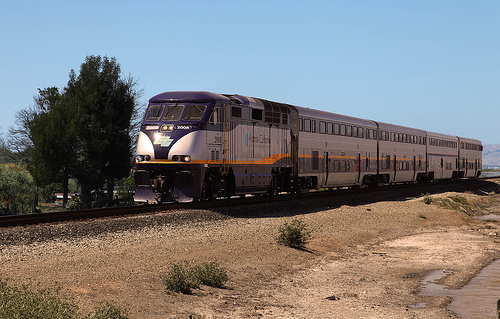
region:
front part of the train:
[121, 79, 233, 211]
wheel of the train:
[269, 160, 310, 209]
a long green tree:
[16, 37, 155, 202]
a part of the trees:
[145, 238, 242, 310]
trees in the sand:
[132, 238, 233, 308]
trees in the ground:
[141, 235, 246, 311]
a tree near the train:
[268, 203, 323, 269]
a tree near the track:
[254, 184, 357, 312]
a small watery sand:
[389, 220, 474, 315]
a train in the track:
[125, 83, 482, 225]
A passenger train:
[128, 85, 499, 230]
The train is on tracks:
[11, 74, 498, 222]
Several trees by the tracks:
[32, 52, 135, 206]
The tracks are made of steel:
[10, 190, 140, 231]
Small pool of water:
[431, 235, 498, 315]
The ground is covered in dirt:
[53, 211, 433, 317]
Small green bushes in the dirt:
[154, 213, 314, 292]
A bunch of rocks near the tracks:
[21, 203, 200, 240]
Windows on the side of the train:
[294, 111, 484, 154]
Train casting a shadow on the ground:
[233, 177, 480, 212]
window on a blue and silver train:
[182, 102, 210, 125]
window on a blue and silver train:
[162, 100, 185, 122]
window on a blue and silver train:
[144, 102, 166, 123]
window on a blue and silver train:
[230, 102, 244, 118]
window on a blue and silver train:
[210, 104, 227, 127]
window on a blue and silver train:
[302, 114, 312, 134]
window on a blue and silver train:
[317, 117, 325, 135]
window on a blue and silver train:
[339, 120, 345, 137]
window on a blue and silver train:
[367, 125, 375, 140]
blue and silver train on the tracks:
[130, 74, 491, 211]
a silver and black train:
[122, 76, 487, 237]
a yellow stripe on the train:
[146, 140, 448, 181]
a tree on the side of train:
[7, 51, 157, 250]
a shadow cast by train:
[205, 177, 497, 224]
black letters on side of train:
[247, 128, 279, 150]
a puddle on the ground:
[407, 244, 483, 316]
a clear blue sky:
[13, 8, 498, 153]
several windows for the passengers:
[295, 112, 485, 159]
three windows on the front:
[142, 97, 202, 134]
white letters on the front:
[145, 129, 175, 159]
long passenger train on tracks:
[134, 80, 485, 208]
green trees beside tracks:
[7, 49, 144, 211]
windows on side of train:
[299, 114, 483, 156]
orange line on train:
[201, 151, 295, 166]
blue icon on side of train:
[239, 126, 254, 150]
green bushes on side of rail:
[161, 251, 237, 298]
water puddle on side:
[407, 226, 497, 317]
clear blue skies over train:
[0, 3, 496, 109]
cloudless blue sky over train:
[0, 1, 496, 101]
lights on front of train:
[132, 151, 197, 166]